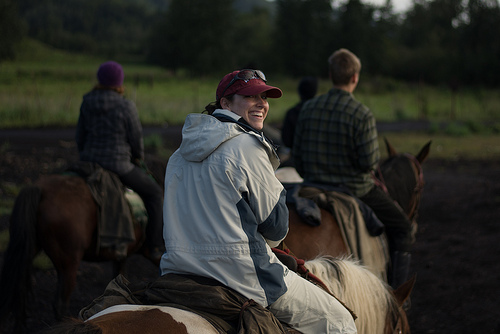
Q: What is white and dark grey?
A: Lightweight jacket.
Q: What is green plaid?
A: Flannel.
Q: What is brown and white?
A: The horse.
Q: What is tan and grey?
A: Hooded coat.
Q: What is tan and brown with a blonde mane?
A: The horse.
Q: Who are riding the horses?
A: Four people.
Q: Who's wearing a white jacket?
A: The woman.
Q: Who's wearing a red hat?
A: The woman.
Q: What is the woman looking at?
A: Camera.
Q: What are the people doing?
A: Riding horses.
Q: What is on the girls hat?
A: Sunglasses.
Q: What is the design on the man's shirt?
A: Plaid.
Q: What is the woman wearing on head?
A: Hat.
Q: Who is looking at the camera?
A: Lady.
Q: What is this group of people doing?
A: Riding horses.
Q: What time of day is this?
A: Evening.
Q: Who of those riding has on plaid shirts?
A: 2.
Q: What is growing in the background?
A: Trees are in the background.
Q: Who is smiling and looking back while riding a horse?
A: A woman wearing a tan and blue hooded jacket.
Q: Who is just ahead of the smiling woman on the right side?
A: A blond haired man on horseback.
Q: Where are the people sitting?
A: On horses.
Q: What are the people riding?
A: Horses.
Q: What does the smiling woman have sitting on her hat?
A: Glasses.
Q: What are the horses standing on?
A: Dirt.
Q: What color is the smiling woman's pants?
A: White.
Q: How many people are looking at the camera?
A: One.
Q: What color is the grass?
A: Green.